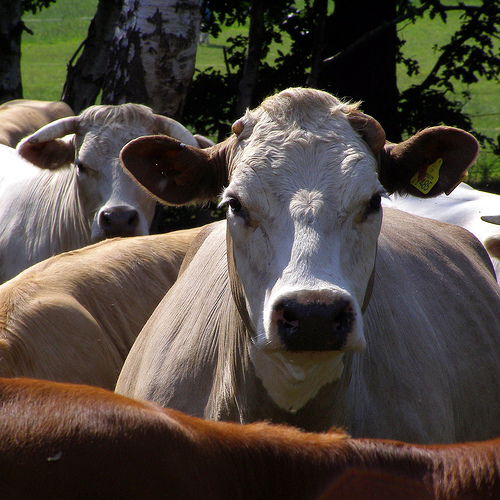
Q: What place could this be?
A: It is a field.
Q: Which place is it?
A: It is a field.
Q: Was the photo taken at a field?
A: Yes, it was taken in a field.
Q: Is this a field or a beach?
A: It is a field.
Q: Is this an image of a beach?
A: No, the picture is showing a field.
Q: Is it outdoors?
A: Yes, it is outdoors.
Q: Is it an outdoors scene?
A: Yes, it is outdoors.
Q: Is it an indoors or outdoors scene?
A: It is outdoors.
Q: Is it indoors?
A: No, it is outdoors.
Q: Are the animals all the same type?
A: Yes, all the animals are cows.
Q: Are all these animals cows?
A: Yes, all the animals are cows.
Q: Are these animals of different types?
A: No, all the animals are cows.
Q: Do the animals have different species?
A: No, all the animals are cows.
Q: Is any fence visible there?
A: No, there are no fences.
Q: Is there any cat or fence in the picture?
A: No, there are no fences or cats.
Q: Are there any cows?
A: Yes, there is a cow.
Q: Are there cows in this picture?
A: Yes, there is a cow.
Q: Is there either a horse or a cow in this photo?
A: Yes, there is a cow.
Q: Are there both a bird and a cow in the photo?
A: No, there is a cow but no birds.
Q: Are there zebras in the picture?
A: No, there are no zebras.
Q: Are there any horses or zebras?
A: No, there are no zebras or horses.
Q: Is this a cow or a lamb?
A: This is a cow.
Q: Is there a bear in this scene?
A: No, there are no bears.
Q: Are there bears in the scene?
A: No, there are no bears.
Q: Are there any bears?
A: No, there are no bears.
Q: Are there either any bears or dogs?
A: No, there are no bears or dogs.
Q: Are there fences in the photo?
A: No, there are no fences.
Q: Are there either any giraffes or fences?
A: No, there are no fences or giraffes.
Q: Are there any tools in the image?
A: No, there are no tools.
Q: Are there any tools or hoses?
A: No, there are no tools or hoses.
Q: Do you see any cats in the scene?
A: No, there are no cats.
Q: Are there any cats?
A: No, there are no cats.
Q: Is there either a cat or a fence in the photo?
A: No, there are no cats or fences.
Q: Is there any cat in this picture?
A: No, there are no cats.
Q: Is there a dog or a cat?
A: No, there are no cats or dogs.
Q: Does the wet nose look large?
A: Yes, the nose is large.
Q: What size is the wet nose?
A: The nose is large.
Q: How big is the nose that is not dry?
A: The nose is large.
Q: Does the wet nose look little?
A: No, the nose is large.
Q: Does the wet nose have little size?
A: No, the nose is large.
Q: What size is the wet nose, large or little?
A: The nose is large.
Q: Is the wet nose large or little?
A: The nose is large.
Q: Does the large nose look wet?
A: Yes, the nose is wet.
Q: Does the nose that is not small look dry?
A: No, the nose is wet.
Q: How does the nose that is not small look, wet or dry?
A: The nose is wet.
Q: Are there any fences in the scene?
A: No, there are no fences.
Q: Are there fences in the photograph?
A: No, there are no fences.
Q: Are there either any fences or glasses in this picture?
A: No, there are no fences or glasses.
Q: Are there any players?
A: No, there are no players.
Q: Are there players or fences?
A: No, there are no players or fences.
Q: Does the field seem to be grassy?
A: Yes, the field is grassy.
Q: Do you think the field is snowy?
A: No, the field is grassy.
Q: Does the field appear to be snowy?
A: No, the field is grassy.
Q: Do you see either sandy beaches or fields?
A: No, there is a field but it is grassy.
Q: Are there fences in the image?
A: No, there are no fences.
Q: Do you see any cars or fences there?
A: No, there are no fences or cars.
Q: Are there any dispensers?
A: No, there are no dispensers.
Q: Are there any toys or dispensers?
A: No, there are no dispensers or toys.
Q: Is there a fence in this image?
A: No, there are no fences.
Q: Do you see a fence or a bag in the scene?
A: No, there are no fences or bags.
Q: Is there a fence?
A: No, there are no fences.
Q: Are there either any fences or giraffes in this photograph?
A: No, there are no fences or giraffes.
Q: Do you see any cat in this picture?
A: No, there are no cats.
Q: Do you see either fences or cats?
A: No, there are no cats or fences.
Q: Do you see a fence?
A: No, there are no fences.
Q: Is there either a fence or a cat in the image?
A: No, there are no fences or cats.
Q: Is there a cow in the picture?
A: Yes, there are cows.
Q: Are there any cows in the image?
A: Yes, there are cows.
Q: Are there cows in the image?
A: Yes, there are cows.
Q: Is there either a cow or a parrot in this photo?
A: Yes, there are cows.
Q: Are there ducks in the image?
A: No, there are no ducks.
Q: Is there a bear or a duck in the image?
A: No, there are no ducks or bears.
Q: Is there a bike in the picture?
A: No, there are no bikes.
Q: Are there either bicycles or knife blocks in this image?
A: No, there are no bicycles or knife blocks.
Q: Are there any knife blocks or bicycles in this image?
A: No, there are no bicycles or knife blocks.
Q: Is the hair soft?
A: Yes, the hair is soft.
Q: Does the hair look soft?
A: Yes, the hair is soft.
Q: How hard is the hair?
A: The hair is soft.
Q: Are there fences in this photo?
A: No, there are no fences.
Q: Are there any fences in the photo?
A: No, there are no fences.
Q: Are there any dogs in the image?
A: No, there are no dogs.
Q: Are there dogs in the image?
A: No, there are no dogs.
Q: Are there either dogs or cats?
A: No, there are no dogs or cats.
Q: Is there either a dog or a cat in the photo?
A: No, there are no dogs or cats.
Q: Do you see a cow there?
A: Yes, there is a cow.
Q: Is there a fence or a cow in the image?
A: Yes, there is a cow.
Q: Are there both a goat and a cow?
A: No, there is a cow but no goats.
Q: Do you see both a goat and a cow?
A: No, there is a cow but no goats.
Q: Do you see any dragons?
A: No, there are no dragons.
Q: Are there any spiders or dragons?
A: No, there are no dragons or spiders.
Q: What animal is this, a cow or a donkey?
A: This is a cow.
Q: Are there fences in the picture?
A: No, there are no fences.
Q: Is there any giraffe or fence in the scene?
A: No, there are no fences or giraffes.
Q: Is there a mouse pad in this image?
A: No, there are no mouse pads.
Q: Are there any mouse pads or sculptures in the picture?
A: No, there are no mouse pads or sculptures.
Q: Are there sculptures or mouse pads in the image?
A: No, there are no mouse pads or sculptures.